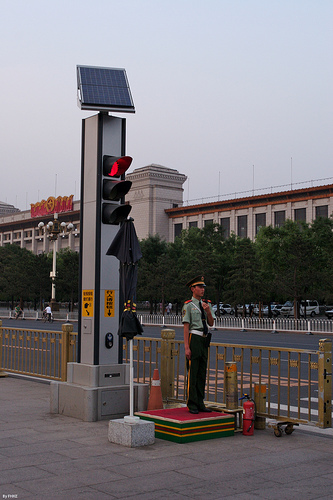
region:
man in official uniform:
[180, 275, 211, 412]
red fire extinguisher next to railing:
[239, 393, 257, 436]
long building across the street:
[5, 158, 332, 252]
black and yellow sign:
[80, 286, 117, 322]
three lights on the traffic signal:
[103, 151, 130, 224]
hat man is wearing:
[184, 274, 205, 288]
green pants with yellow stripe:
[185, 333, 209, 405]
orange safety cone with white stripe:
[142, 369, 168, 418]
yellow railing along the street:
[2, 326, 331, 415]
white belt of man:
[191, 328, 208, 338]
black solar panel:
[71, 51, 140, 116]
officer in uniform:
[171, 266, 223, 411]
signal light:
[93, 142, 133, 246]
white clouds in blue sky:
[10, 19, 33, 54]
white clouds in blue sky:
[151, 54, 187, 86]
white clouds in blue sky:
[221, 91, 268, 142]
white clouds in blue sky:
[205, 76, 226, 115]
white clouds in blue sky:
[255, 73, 282, 105]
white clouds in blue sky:
[7, 130, 50, 168]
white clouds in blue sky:
[198, 60, 236, 111]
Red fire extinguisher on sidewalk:
[238, 391, 257, 436]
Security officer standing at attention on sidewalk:
[181, 272, 216, 414]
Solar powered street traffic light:
[66, 63, 137, 375]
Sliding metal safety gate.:
[1, 323, 332, 429]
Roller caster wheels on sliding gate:
[270, 419, 300, 436]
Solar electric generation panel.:
[74, 63, 136, 112]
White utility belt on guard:
[188, 328, 212, 338]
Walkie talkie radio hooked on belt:
[205, 330, 213, 347]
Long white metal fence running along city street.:
[0, 307, 332, 335]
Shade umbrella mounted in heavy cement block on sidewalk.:
[104, 217, 157, 448]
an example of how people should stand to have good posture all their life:
[181, 274, 215, 415]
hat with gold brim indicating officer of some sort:
[185, 275, 205, 286]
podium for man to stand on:
[137, 407, 237, 440]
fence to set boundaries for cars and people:
[3, 333, 326, 407]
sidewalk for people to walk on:
[3, 444, 257, 496]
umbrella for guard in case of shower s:
[112, 219, 153, 443]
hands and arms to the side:
[181, 297, 191, 359]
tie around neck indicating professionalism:
[198, 297, 207, 339]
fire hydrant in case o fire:
[239, 389, 258, 436]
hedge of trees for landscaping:
[4, 240, 326, 311]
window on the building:
[232, 215, 244, 234]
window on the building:
[258, 212, 267, 231]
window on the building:
[171, 221, 186, 244]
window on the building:
[250, 212, 264, 234]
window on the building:
[274, 214, 283, 229]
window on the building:
[276, 214, 281, 227]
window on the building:
[294, 211, 308, 225]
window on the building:
[290, 206, 308, 231]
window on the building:
[316, 207, 328, 222]